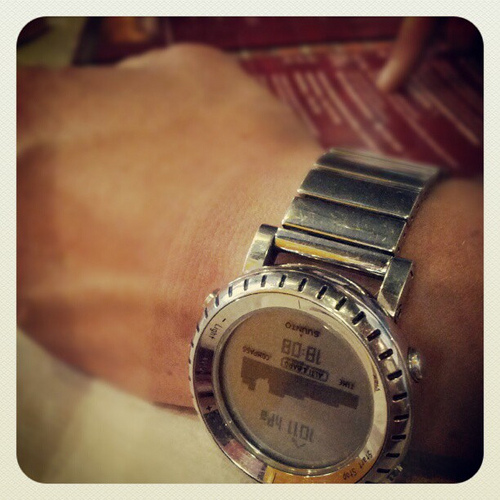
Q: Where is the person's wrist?
A: On table.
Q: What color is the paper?
A: Red.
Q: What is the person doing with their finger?
A: Pointing to paper.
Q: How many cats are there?
A: None.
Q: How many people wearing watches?
A: One.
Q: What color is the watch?
A: Silver.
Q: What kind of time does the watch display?
A: Military time.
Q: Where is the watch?
A: On person's wrist.